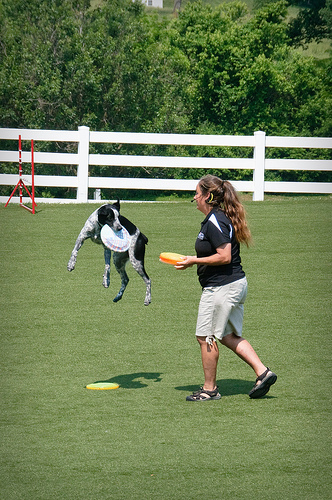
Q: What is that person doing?
A: Throwing frisbees at the dog.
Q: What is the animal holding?
A: A frisbee.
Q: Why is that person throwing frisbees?
A: To play with the dog.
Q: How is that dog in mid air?
A: By jumping for the frisbee.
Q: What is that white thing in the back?
A: Painted fences.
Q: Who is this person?
A: A dog trainer.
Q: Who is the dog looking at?
A: The dog trainer.